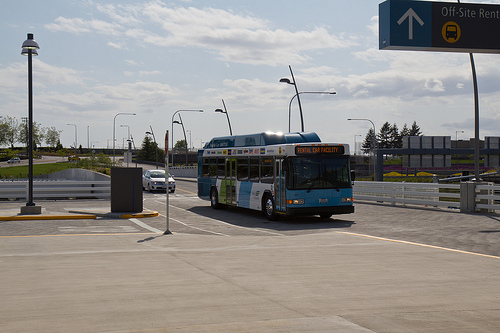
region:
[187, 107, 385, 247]
a bus on a roadway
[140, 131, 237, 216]
a car behind a bus on a road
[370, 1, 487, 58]
a street sign with a arrow on it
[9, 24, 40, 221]
a street light on a ple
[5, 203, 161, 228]
a curb painted yellow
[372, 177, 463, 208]
a white fence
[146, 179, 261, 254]
white lines painted on a road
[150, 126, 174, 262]
a traffic sign on a curb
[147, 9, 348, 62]
white clouds in the sky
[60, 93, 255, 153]
several street lights next to a road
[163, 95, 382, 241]
bus on the ground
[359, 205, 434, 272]
white line on ground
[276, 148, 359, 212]
front window of bus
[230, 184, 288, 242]
wheel of the bus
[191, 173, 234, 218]
back tire of bus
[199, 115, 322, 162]
top of the bus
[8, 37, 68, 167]
pole next to street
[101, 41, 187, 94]
sky above the land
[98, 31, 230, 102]
clouds in the sky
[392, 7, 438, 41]
white arrow pointing up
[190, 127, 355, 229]
Bus on the road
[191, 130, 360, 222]
Bus is on the road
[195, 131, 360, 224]
Bus on the street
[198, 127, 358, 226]
Bus is on the street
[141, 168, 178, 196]
Car on the road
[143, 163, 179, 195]
Car is on the road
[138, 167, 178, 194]
Car is on the street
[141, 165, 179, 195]
Car on the street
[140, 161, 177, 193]
White car is on the street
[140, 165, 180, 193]
White car is on the road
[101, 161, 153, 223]
A street utility box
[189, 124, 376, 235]
A bus in transit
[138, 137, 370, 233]
A white car behind a bus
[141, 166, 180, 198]
A distant white car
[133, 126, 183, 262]
A stop sign in profile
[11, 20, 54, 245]
a street light on a median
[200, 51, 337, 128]
Two street lamps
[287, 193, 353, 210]
front headlights of a bus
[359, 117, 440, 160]
five distant conifer trees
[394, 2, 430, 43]
an upward pointing arrow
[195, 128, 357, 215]
a multicolored bus on the street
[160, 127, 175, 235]
A stop sign at the corner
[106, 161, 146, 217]
An electrical utility box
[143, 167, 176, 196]
A white car behind the bus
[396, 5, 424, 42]
A white arrow pointing up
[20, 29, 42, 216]
A double lamp post on the sidewalk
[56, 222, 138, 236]
The word stop painted in white on the road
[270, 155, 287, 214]
The front double doors of the bus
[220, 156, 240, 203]
The side double doors of the bus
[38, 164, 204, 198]
A cement bridge